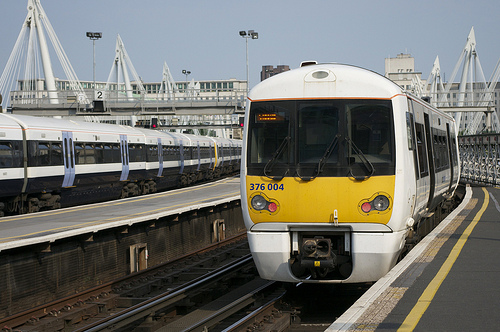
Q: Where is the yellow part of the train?
A: On the front.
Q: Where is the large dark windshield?
A: On the train.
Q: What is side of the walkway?
A: Yellow line.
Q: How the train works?
A: Track.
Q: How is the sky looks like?
A: Clear blue.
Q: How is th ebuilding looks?
A: Large.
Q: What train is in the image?
A: Passenger train.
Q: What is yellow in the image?
A: Caution line.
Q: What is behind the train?
A: Buildings.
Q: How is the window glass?
A: Dark.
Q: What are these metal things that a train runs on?
A: Tracks.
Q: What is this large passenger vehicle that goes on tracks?
A: Train.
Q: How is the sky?
A: Hazy.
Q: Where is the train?
A: On the tracks.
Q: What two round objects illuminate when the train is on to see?
A: Lights.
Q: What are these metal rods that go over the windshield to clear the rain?
A: Windshield wipers.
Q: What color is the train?
A: White,yellow, and black.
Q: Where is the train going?
A: To canada.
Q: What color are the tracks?
A: Black.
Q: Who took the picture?
A: A tourist.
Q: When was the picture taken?
A: In the afternoon.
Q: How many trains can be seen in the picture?
A: Two.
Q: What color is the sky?
A: Blue.